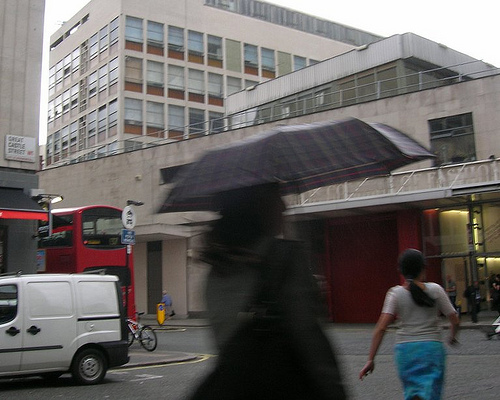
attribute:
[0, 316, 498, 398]
street — paved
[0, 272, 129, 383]
van — here, white, parked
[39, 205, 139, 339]
bus — here, red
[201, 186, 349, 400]
lady — here, walking, crossing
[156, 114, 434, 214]
umbrella — black, here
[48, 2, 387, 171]
building — here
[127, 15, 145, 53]
window — rectangular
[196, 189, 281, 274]
hair — here, long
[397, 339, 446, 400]
skirt — blue